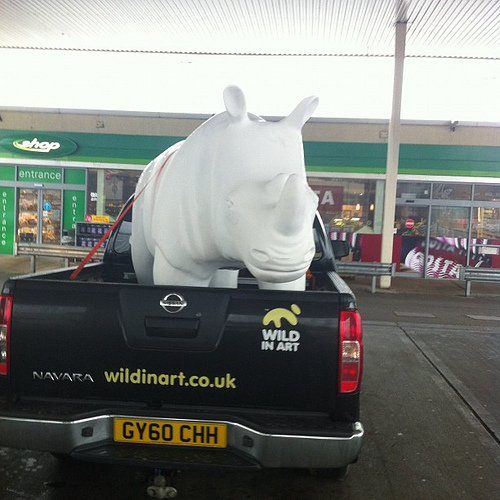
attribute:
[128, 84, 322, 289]
rhino — plastic, sculpted, white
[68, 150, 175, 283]
strap — red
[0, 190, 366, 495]
truck — black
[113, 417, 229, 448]
license — yellow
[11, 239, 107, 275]
railing — metal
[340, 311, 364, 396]
tail light — red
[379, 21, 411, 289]
post — metal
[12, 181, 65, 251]
door — sliding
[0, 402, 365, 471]
bumper — silver, metal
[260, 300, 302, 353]
logo — yellow, white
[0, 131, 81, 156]
sign — green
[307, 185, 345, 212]
poster — pink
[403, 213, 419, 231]
caution sign — red